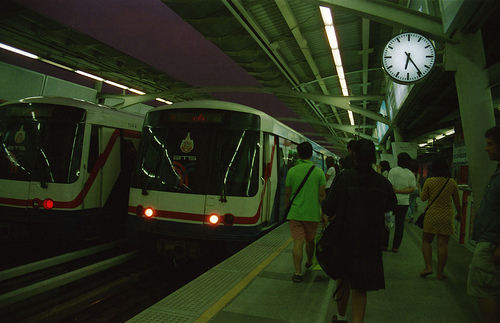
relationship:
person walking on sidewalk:
[413, 156, 463, 281] [125, 209, 494, 316]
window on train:
[125, 96, 337, 267] [209, 127, 256, 195]